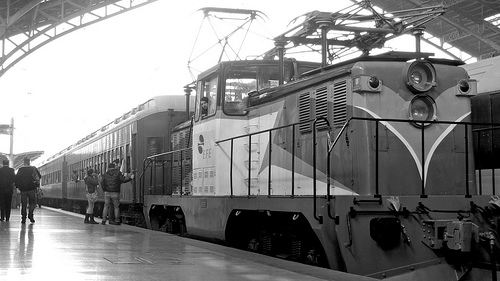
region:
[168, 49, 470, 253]
engine of the train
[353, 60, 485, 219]
V shape detail on engine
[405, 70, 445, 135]
two front headloghts on train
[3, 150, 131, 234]
passengers at the train station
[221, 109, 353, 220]
black hand rails around the engine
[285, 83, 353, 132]
vents on the side of the engine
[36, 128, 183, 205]
passenger cars on the train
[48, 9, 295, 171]
open roof of the train station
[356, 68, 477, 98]
two small lights on the side of the train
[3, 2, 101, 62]
beams overhead to support roof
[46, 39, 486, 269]
train at a station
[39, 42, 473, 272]
passenger train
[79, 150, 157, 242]
people boarding a train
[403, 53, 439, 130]
front lights of a train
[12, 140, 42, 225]
man in a black jacket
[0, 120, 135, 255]
people on a train platform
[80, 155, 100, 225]
woman next to a train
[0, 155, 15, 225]
man in a black suit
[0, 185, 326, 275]
train platform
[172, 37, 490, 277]
front train car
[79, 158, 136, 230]
two people approaching the train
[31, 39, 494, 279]
a passanger train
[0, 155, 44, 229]
pair of people walking along the platform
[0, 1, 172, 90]
girders supporting the roof of the train station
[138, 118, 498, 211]
railing around the front car of the train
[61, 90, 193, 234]
passenger car of the train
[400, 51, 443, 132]
two headlights on the front of thr train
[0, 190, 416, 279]
train station platform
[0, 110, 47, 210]
shelter over part of the platform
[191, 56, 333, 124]
windows on the front train car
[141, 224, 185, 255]
part of a floor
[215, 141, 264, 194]
part of a balcony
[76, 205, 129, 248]
part of a floor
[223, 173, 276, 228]
part of a traion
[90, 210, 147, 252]
part of a floor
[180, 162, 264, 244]
edge of a train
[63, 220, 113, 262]
part of a floor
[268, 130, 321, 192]
part of a train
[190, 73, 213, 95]
part of a window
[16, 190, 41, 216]
a person wearing jeans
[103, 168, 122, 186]
a person wearing a jacket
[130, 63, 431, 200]
a train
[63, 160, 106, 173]
windows on the train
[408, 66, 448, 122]
headlights on the train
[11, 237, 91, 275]
a reflection of light on the ground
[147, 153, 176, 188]
railings on the train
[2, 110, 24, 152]
a pole in the air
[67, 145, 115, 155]
reflection of light on the train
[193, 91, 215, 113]
a person on the train